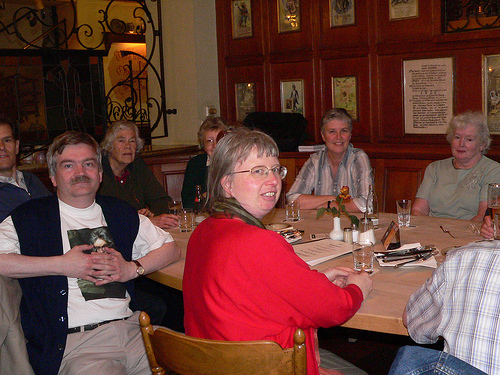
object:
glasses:
[227, 165, 288, 180]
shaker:
[365, 185, 372, 232]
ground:
[391, 182, 399, 198]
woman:
[182, 128, 374, 373]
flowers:
[316, 186, 360, 229]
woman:
[409, 111, 500, 220]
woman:
[285, 107, 374, 213]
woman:
[181, 116, 230, 214]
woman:
[101, 121, 179, 228]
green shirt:
[415, 155, 498, 220]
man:
[0, 130, 182, 375]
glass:
[396, 199, 411, 228]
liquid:
[398, 213, 411, 229]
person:
[389, 241, 500, 374]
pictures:
[230, 0, 500, 135]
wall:
[213, 1, 497, 214]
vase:
[330, 217, 344, 241]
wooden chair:
[137, 311, 307, 375]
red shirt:
[183, 213, 365, 375]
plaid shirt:
[406, 239, 500, 375]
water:
[353, 253, 374, 272]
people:
[0, 106, 500, 375]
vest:
[0, 198, 175, 329]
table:
[142, 198, 500, 337]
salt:
[351, 218, 377, 275]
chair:
[0, 274, 36, 375]